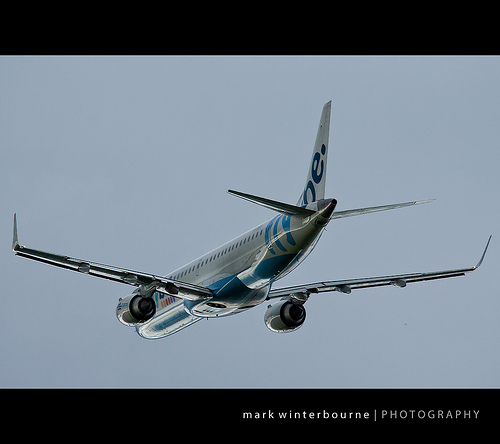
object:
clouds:
[5, 66, 496, 386]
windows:
[166, 218, 266, 275]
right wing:
[265, 234, 492, 334]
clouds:
[422, 346, 490, 377]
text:
[227, 403, 484, 421]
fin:
[302, 99, 329, 206]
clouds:
[319, 335, 482, 385]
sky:
[6, 58, 488, 184]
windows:
[161, 225, 265, 283]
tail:
[229, 97, 435, 224]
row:
[153, 294, 176, 306]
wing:
[8, 210, 215, 315]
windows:
[238, 237, 244, 249]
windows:
[231, 240, 235, 252]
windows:
[258, 225, 263, 237]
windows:
[254, 227, 257, 239]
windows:
[211, 251, 215, 261]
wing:
[265, 235, 495, 331]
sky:
[77, 354, 423, 381]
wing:
[330, 191, 440, 225]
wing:
[220, 186, 315, 232]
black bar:
[1, 3, 498, 56]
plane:
[12, 100, 491, 338]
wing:
[271, 233, 493, 297]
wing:
[11, 212, 212, 300]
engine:
[114, 293, 156, 325]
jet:
[0, 100, 488, 386]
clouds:
[79, 100, 369, 185]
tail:
[298, 88, 338, 212]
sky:
[0, 54, 500, 390]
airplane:
[1, 95, 498, 335]